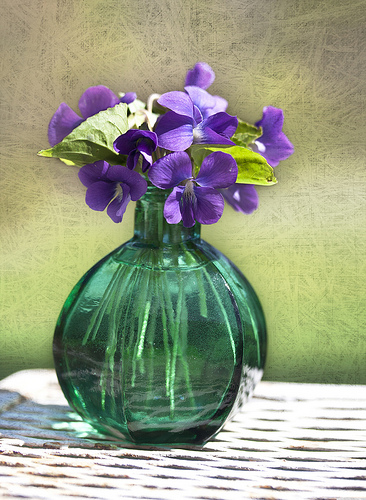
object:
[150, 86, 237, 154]
flower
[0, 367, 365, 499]
metal table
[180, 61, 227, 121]
flower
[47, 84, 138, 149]
flowers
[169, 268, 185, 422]
stems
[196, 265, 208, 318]
stems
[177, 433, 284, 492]
grate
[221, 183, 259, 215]
flower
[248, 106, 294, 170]
flower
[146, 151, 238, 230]
flower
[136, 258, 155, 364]
stems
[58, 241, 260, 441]
water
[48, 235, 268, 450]
water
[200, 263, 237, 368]
green stems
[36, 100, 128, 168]
leaf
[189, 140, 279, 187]
leaf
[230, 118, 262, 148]
leaf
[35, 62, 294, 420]
bouquet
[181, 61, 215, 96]
rose petals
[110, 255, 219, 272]
water line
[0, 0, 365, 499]
background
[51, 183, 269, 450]
vase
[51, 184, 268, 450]
glass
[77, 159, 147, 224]
flower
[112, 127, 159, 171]
flower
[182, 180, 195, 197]
center